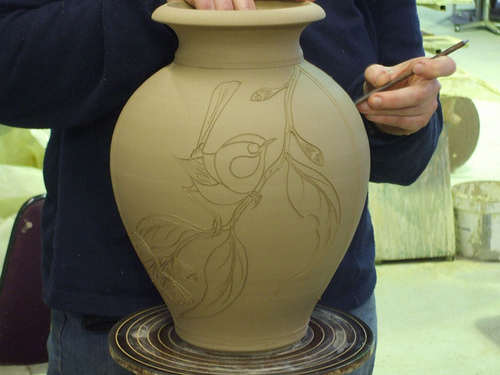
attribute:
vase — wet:
[107, 1, 373, 350]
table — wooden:
[377, 97, 466, 270]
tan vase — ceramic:
[109, 1, 371, 354]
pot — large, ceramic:
[98, 9, 413, 356]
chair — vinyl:
[0, 188, 52, 374]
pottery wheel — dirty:
[115, 320, 370, 374]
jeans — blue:
[47, 291, 374, 373]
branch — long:
[119, 121, 306, 311]